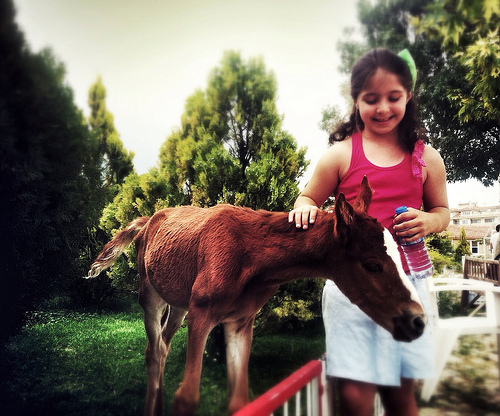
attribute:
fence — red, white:
[210, 351, 395, 411]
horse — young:
[80, 172, 426, 414]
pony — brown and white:
[91, 208, 423, 411]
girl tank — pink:
[313, 66, 445, 209]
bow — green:
[396, 38, 427, 100]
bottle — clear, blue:
[389, 187, 483, 277]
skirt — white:
[319, 267, 438, 382]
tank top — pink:
[338, 138, 441, 262]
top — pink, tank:
[339, 141, 429, 268]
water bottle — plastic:
[395, 207, 435, 280]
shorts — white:
[321, 272, 441, 385]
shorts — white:
[342, 220, 492, 377]